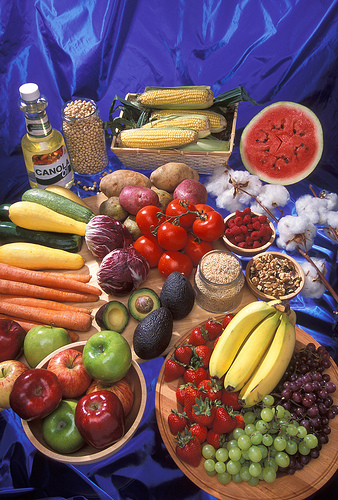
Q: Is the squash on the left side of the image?
A: Yes, the squash is on the left of the image.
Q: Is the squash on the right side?
A: No, the squash is on the left of the image.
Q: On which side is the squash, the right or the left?
A: The squash is on the left of the image.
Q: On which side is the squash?
A: The squash is on the left of the image.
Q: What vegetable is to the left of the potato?
A: The vegetable is a squash.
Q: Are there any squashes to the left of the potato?
A: Yes, there is a squash to the left of the potato.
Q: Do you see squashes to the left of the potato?
A: Yes, there is a squash to the left of the potato.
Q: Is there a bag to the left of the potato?
A: No, there is a squash to the left of the potato.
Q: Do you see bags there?
A: No, there are no bags.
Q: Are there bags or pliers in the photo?
A: No, there are no bags or pliers.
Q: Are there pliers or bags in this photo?
A: No, there are no bags or pliers.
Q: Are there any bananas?
A: Yes, there is a banana.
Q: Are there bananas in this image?
A: Yes, there is a banana.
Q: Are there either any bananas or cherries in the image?
A: Yes, there is a banana.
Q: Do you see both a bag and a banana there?
A: No, there is a banana but no bags.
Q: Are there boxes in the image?
A: No, there are no boxes.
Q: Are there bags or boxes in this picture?
A: No, there are no boxes or bags.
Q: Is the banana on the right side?
A: Yes, the banana is on the right of the image.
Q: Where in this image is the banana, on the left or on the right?
A: The banana is on the right of the image.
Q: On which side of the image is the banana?
A: The banana is on the right of the image.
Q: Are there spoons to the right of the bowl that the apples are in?
A: No, there is a banana to the right of the bowl.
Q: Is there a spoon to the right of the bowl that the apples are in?
A: No, there is a banana to the right of the bowl.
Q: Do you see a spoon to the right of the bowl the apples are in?
A: No, there is a banana to the right of the bowl.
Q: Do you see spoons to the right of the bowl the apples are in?
A: No, there is a banana to the right of the bowl.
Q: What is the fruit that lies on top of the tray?
A: The fruit is a banana.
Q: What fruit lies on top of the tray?
A: The fruit is a banana.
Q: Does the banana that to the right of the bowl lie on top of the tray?
A: Yes, the banana lies on top of the tray.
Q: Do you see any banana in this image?
A: Yes, there is a banana.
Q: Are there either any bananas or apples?
A: Yes, there is a banana.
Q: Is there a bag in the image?
A: No, there are no bags.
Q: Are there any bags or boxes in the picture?
A: No, there are no bags or boxes.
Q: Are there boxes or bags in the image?
A: No, there are no bags or boxes.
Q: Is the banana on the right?
A: Yes, the banana is on the right of the image.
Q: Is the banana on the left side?
A: No, the banana is on the right of the image.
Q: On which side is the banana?
A: The banana is on the right of the image.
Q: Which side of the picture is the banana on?
A: The banana is on the right of the image.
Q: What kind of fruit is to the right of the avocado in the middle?
A: The fruit is a banana.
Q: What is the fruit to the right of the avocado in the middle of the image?
A: The fruit is a banana.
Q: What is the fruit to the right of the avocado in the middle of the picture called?
A: The fruit is a banana.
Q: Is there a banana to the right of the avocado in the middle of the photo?
A: Yes, there is a banana to the right of the avocado.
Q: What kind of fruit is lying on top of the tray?
A: The fruit is a banana.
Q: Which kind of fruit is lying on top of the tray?
A: The fruit is a banana.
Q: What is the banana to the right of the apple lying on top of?
A: The banana is lying on top of the tray.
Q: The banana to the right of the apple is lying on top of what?
A: The banana is lying on top of the tray.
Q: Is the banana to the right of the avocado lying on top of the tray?
A: Yes, the banana is lying on top of the tray.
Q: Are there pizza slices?
A: No, there are no pizza slices.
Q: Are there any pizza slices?
A: No, there are no pizza slices.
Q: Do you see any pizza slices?
A: No, there are no pizza slices.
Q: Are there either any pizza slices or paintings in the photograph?
A: No, there are no pizza slices or paintings.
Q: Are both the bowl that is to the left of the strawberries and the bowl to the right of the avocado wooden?
A: Yes, both the bowl and the bowl are wooden.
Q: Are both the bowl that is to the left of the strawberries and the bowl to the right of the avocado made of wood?
A: Yes, both the bowl and the bowl are made of wood.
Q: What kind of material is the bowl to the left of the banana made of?
A: The bowl is made of wood.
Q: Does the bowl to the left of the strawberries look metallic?
A: No, the bowl is wooden.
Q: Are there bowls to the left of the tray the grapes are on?
A: Yes, there is a bowl to the left of the tray.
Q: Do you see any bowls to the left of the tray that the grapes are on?
A: Yes, there is a bowl to the left of the tray.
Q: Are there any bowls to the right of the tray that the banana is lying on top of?
A: No, the bowl is to the left of the tray.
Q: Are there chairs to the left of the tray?
A: No, there is a bowl to the left of the tray.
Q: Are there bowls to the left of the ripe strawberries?
A: Yes, there is a bowl to the left of the strawberries.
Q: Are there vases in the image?
A: No, there are no vases.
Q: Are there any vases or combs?
A: No, there are no vases or combs.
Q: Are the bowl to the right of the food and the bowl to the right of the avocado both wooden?
A: Yes, both the bowl and the bowl are wooden.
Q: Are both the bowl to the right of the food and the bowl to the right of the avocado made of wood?
A: Yes, both the bowl and the bowl are made of wood.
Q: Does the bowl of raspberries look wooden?
A: Yes, the bowl is wooden.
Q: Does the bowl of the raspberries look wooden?
A: Yes, the bowl is wooden.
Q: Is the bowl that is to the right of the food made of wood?
A: Yes, the bowl is made of wood.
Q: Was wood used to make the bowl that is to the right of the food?
A: Yes, the bowl is made of wood.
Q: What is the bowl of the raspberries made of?
A: The bowl is made of wood.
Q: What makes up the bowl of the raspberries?
A: The bowl is made of wood.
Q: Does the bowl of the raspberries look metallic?
A: No, the bowl is wooden.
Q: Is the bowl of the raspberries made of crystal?
A: No, the bowl is made of wood.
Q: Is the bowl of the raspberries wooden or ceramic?
A: The bowl is wooden.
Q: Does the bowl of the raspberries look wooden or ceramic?
A: The bowl is wooden.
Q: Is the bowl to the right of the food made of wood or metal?
A: The bowl is made of wood.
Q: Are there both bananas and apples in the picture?
A: Yes, there are both an apple and a banana.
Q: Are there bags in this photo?
A: No, there are no bags.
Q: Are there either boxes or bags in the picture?
A: No, there are no bags or boxes.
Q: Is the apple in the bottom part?
A: Yes, the apple is in the bottom of the image.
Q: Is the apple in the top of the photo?
A: No, the apple is in the bottom of the image.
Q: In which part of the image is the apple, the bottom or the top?
A: The apple is in the bottom of the image.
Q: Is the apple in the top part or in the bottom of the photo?
A: The apple is in the bottom of the image.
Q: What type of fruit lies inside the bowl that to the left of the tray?
A: The fruit is an apple.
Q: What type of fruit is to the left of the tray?
A: The fruit is an apple.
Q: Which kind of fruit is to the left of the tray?
A: The fruit is an apple.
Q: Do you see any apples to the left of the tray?
A: Yes, there is an apple to the left of the tray.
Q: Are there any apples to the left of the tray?
A: Yes, there is an apple to the left of the tray.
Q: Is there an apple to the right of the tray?
A: No, the apple is to the left of the tray.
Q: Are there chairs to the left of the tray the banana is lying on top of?
A: No, there is an apple to the left of the tray.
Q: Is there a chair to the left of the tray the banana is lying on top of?
A: No, there is an apple to the left of the tray.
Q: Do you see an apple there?
A: Yes, there is an apple.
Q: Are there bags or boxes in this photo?
A: No, there are no bags or boxes.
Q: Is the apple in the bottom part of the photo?
A: Yes, the apple is in the bottom of the image.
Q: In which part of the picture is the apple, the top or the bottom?
A: The apple is in the bottom of the image.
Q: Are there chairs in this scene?
A: No, there are no chairs.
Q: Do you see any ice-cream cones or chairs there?
A: No, there are no chairs or ice-cream cones.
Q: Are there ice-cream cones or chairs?
A: No, there are no chairs or ice-cream cones.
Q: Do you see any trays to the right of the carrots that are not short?
A: Yes, there is a tray to the right of the carrots.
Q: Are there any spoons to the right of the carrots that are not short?
A: No, there is a tray to the right of the carrots.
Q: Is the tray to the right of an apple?
A: Yes, the tray is to the right of an apple.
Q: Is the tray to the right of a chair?
A: No, the tray is to the right of an apple.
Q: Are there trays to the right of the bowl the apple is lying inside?
A: Yes, there is a tray to the right of the bowl.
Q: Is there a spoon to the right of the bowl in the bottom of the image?
A: No, there is a tray to the right of the bowl.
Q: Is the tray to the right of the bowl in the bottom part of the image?
A: Yes, the tray is to the right of the bowl.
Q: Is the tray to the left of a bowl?
A: No, the tray is to the right of a bowl.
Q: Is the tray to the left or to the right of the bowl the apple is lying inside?
A: The tray is to the right of the bowl.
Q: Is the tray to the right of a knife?
A: No, the tray is to the right of an apple.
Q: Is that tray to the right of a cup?
A: No, the tray is to the right of an apple.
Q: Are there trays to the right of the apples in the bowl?
A: Yes, there is a tray to the right of the apples.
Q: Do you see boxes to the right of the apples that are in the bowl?
A: No, there is a tray to the right of the apples.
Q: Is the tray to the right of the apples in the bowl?
A: Yes, the tray is to the right of the apples.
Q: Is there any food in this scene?
A: Yes, there is food.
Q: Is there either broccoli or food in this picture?
A: Yes, there is food.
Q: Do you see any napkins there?
A: No, there are no napkins.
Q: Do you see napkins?
A: No, there are no napkins.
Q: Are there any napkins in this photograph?
A: No, there are no napkins.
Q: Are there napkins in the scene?
A: No, there are no napkins.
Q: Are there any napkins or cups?
A: No, there are no napkins or cups.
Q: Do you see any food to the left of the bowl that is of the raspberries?
A: Yes, there is food to the left of the bowl.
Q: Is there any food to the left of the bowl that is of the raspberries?
A: Yes, there is food to the left of the bowl.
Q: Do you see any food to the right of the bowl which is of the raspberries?
A: No, the food is to the left of the bowl.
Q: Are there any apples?
A: Yes, there is an apple.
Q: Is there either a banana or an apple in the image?
A: Yes, there is an apple.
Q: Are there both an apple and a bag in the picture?
A: No, there is an apple but no bags.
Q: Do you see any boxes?
A: No, there are no boxes.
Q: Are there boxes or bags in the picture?
A: No, there are no boxes or bags.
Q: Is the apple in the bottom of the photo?
A: Yes, the apple is in the bottom of the image.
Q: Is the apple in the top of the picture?
A: No, the apple is in the bottom of the image.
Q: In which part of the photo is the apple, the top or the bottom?
A: The apple is in the bottom of the image.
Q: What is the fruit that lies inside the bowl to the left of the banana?
A: The fruit is an apple.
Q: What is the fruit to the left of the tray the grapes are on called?
A: The fruit is an apple.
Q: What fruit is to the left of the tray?
A: The fruit is an apple.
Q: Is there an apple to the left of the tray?
A: Yes, there is an apple to the left of the tray.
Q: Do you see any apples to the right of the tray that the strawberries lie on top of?
A: No, the apple is to the left of the tray.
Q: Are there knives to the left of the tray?
A: No, there is an apple to the left of the tray.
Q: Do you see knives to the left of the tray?
A: No, there is an apple to the left of the tray.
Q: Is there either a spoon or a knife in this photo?
A: No, there are no spoons or knives.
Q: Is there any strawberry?
A: Yes, there are strawberries.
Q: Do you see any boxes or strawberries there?
A: Yes, there are strawberries.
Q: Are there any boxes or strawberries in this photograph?
A: Yes, there are strawberries.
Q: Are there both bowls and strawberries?
A: Yes, there are both strawberries and a bowl.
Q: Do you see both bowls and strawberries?
A: Yes, there are both strawberries and a bowl.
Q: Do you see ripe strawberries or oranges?
A: Yes, there are ripe strawberries.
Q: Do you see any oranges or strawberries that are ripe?
A: Yes, the strawberries are ripe.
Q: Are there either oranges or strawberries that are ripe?
A: Yes, the strawberries are ripe.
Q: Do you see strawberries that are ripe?
A: Yes, there are ripe strawberries.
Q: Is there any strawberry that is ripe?
A: Yes, there are strawberries that are ripe.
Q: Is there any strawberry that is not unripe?
A: Yes, there are ripe strawberries.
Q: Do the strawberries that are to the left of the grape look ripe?
A: Yes, the strawberries are ripe.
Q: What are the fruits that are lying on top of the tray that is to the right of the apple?
A: The fruits are strawberries.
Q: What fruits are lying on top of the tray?
A: The fruits are strawberries.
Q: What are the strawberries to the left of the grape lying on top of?
A: The strawberries are lying on top of the tray.